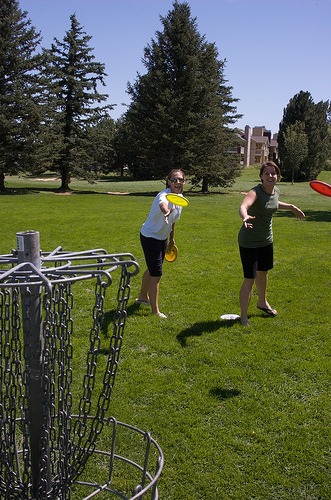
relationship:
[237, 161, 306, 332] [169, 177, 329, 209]
person throwing frisbees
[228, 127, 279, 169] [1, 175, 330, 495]
houses behind field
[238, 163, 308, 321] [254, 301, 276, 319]
woman wearing shoe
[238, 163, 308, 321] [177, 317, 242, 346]
person has shadow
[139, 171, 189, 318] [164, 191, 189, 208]
woman throwing frisbees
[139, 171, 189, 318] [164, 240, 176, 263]
woman holding frisbee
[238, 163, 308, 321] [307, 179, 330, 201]
woman threw frisbee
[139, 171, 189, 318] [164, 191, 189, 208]
woman threw frisbees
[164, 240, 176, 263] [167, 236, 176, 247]
frisbee held in hand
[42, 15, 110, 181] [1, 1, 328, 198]
pine tree visible in background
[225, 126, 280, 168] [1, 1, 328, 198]
building visible in background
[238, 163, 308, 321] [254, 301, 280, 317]
woman wearing shoe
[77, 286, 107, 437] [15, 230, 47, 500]
chain hanging from pole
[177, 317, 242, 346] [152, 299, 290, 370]
shadow cast on ground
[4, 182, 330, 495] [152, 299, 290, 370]
grass growing on ground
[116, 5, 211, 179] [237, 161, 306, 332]
tree behind person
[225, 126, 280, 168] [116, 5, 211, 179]
building behind tree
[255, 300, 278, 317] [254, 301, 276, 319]
foot has shoe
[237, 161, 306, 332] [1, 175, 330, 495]
person playing in park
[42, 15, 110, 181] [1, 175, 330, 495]
pine tree growing in park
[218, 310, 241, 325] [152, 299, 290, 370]
frisbee laying on ground